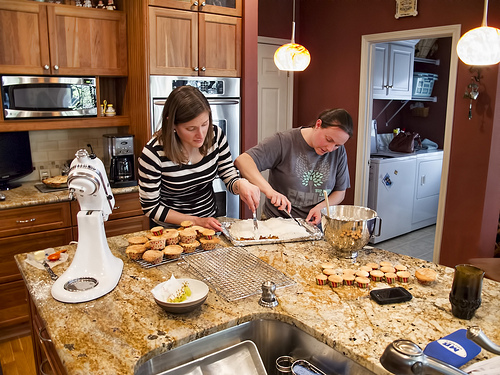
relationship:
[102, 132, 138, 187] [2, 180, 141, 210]
coffee maker on counter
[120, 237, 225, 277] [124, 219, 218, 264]
rack filled with cupcakes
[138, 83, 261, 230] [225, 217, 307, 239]
woman cutting a cake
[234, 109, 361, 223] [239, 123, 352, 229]
woman in shirt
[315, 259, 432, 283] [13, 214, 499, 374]
cupcakes sitting on counter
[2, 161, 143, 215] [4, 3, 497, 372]
counter in kitchen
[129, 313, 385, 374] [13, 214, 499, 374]
sink cut into counter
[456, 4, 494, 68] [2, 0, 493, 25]
light hanging ceiling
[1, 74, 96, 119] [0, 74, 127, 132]
microwave on shelf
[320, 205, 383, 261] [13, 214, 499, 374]
bowl on counter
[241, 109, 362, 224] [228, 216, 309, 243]
woman frosting cake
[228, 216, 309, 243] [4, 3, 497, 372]
cake in kitchen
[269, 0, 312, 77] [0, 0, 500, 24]
lamp hanging from ceiling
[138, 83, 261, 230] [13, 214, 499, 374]
woman working on counter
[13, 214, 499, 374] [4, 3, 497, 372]
counter in kitchen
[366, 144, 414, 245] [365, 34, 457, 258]
washer in laundry room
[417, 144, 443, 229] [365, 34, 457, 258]
dryer in laundry room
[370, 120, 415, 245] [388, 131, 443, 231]
washer next to dryer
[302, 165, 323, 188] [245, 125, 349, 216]
green leaves on shirt